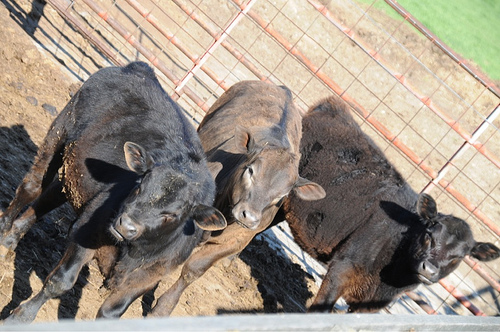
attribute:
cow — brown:
[23, 40, 225, 290]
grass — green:
[432, 9, 485, 41]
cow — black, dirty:
[0, 65, 231, 315]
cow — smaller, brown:
[78, 69, 448, 281]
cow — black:
[286, 87, 498, 319]